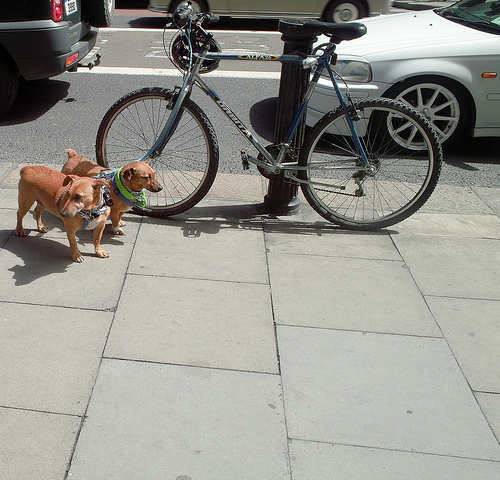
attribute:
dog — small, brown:
[14, 166, 109, 264]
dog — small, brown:
[63, 148, 162, 236]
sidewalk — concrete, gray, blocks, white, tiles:
[0, 162, 499, 479]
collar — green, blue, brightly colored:
[111, 167, 147, 207]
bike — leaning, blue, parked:
[97, 1, 442, 232]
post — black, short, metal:
[264, 17, 322, 214]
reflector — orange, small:
[481, 72, 497, 79]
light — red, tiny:
[73, 52, 79, 63]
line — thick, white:
[80, 65, 299, 79]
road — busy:
[3, 15, 499, 187]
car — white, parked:
[305, 0, 499, 155]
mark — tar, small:
[405, 408, 412, 415]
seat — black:
[302, 20, 366, 43]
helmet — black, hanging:
[172, 31, 221, 74]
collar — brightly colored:
[77, 185, 114, 222]